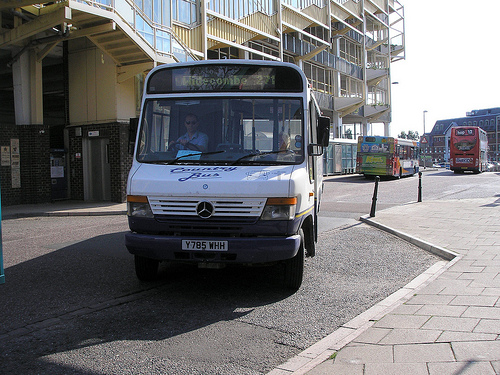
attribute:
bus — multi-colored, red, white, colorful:
[115, 48, 332, 295]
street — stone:
[3, 193, 500, 368]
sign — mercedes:
[192, 198, 217, 223]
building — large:
[3, 5, 412, 125]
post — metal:
[420, 107, 431, 135]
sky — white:
[397, 1, 499, 109]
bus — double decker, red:
[445, 120, 494, 178]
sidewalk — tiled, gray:
[326, 188, 500, 374]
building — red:
[425, 114, 449, 168]